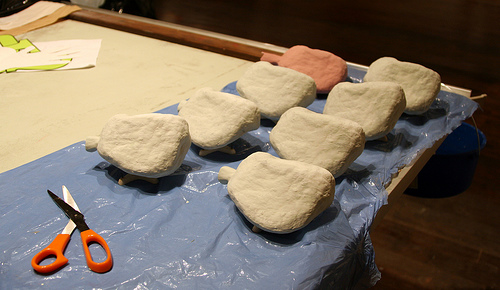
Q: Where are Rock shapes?
A: On cloth.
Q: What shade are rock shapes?
A: White.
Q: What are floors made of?
A: Wood.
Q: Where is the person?
A: Behind table.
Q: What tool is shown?
A: Scissors.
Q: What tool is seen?
A: Scissors.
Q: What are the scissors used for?
A: To cut.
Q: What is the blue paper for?
A: Protect the table.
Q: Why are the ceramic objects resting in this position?
A: To dry.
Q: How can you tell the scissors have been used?
A: Open handle.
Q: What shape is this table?
A: Rectangle.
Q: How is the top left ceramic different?
A: Color.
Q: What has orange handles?
A: Scissors.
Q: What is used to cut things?
A: Scissors.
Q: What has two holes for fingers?
A: Scissors.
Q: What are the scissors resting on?
A: Blue plastic.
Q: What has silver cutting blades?
A: Scissors.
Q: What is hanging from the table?
A: A bucket.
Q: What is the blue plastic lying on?
A: A table.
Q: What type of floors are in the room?
A: Hardwood.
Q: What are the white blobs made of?
A: Clay.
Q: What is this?
A: A craft.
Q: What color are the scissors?
A: Orange.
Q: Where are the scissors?
A: On the table.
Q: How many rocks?
A: 8.